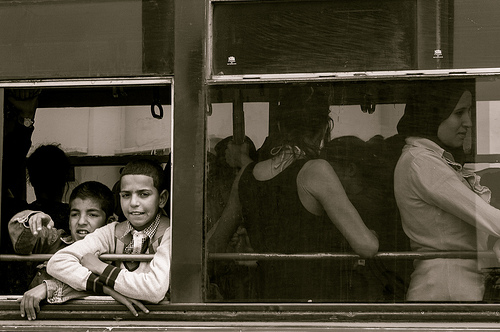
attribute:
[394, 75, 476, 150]
head — draped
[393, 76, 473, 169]
scarf — black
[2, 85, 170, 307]
window — open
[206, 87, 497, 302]
window — closed, glass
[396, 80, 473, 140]
head dress — dark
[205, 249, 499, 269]
rail — metal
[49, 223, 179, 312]
sweater — white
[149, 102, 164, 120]
strap — nylon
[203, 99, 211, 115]
strap — nylon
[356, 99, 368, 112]
strap — nylon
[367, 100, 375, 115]
strap — nylon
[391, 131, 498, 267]
blouse — fluffy, white